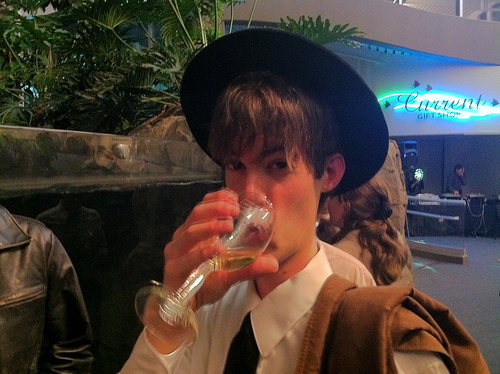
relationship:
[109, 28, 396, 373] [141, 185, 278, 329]
person has hand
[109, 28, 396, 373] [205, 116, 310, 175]
person has bangs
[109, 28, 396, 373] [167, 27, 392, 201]
person wearing hat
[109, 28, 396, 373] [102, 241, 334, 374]
person wearing shirt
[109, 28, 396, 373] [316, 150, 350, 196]
person has ear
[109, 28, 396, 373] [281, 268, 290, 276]
person has mole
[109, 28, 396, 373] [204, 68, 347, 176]
person has hair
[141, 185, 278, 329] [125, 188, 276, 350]
hand holding glass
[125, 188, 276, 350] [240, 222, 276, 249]
glass near mouth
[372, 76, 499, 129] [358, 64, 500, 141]
sign on top of wall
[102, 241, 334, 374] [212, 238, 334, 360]
shirt has collar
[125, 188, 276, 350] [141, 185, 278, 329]
glass in hand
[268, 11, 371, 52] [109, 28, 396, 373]
plant behind person